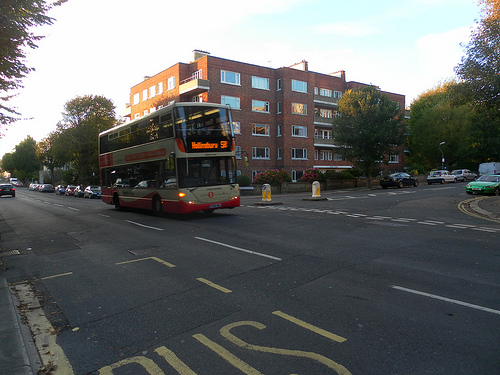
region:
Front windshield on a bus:
[174, 153, 239, 185]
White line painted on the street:
[191, 234, 284, 265]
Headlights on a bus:
[178, 189, 239, 204]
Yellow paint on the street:
[14, 255, 366, 374]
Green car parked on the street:
[465, 171, 499, 192]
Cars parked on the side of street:
[29, 180, 101, 195]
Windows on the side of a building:
[291, 79, 311, 163]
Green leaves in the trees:
[408, 0, 498, 162]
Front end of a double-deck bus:
[144, 100, 243, 218]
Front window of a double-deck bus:
[171, 104, 235, 154]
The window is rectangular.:
[216, 64, 246, 87]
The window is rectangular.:
[248, 69, 273, 92]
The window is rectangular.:
[250, 95, 271, 115]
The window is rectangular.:
[249, 117, 272, 140]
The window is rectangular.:
[247, 143, 273, 161]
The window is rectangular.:
[288, 140, 310, 162]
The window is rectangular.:
[288, 118, 310, 140]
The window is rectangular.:
[288, 98, 309, 119]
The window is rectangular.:
[286, 76, 309, 98]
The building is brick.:
[123, 43, 415, 201]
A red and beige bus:
[92, 95, 243, 222]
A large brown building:
[121, 42, 406, 189]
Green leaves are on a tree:
[325, 81, 410, 191]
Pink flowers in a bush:
[250, 160, 295, 185]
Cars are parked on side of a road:
[22, 172, 107, 202]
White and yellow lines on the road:
[5, 180, 495, 370]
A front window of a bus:
[171, 150, 236, 190]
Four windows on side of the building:
[285, 70, 312, 165]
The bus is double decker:
[90, 95, 241, 220]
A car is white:
[423, 163, 458, 186]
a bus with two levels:
[87, 86, 262, 228]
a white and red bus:
[81, 111, 261, 218]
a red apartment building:
[233, 50, 346, 185]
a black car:
[375, 168, 422, 181]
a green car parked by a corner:
[462, 176, 498, 193]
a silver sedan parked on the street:
[425, 168, 458, 185]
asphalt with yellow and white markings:
[106, 230, 261, 286]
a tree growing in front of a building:
[301, 75, 395, 192]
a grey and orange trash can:
[257, 183, 280, 204]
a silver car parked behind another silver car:
[414, 168, 479, 184]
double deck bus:
[87, 85, 244, 216]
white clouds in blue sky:
[395, 13, 440, 47]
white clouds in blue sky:
[365, 25, 396, 50]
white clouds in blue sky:
[307, 13, 354, 48]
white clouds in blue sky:
[360, 11, 402, 36]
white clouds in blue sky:
[47, 49, 92, 77]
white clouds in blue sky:
[71, 22, 113, 60]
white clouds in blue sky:
[92, 22, 157, 44]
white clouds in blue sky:
[180, 12, 224, 29]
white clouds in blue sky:
[232, 3, 306, 47]